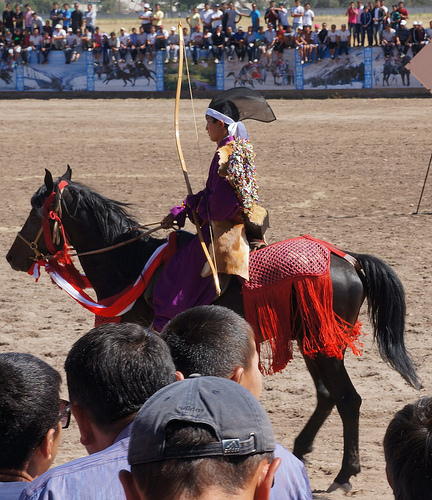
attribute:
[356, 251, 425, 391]
tail — black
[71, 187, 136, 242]
mane — black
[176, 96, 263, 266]
lady — light skinned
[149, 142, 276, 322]
dress — purple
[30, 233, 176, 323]
ribbons — red and white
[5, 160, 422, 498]
horse — black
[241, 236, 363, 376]
blanket — red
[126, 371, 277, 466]
cap — black